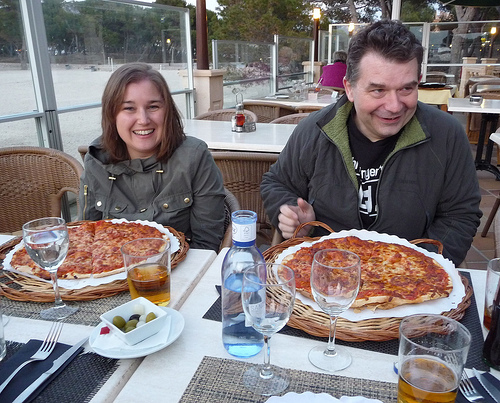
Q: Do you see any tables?
A: Yes, there is a table.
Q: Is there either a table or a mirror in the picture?
A: Yes, there is a table.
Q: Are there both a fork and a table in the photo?
A: Yes, there are both a table and a fork.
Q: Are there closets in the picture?
A: No, there are no closets.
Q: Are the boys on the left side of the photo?
A: Yes, the boys are on the left of the image.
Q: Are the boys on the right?
A: No, the boys are on the left of the image.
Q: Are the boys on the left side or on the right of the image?
A: The boys are on the left of the image.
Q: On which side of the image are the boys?
A: The boys are on the left of the image.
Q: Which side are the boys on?
A: The boys are on the left of the image.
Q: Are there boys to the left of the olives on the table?
A: Yes, there are boys to the left of the olives.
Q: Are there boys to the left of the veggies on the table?
A: Yes, there are boys to the left of the olives.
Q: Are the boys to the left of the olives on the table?
A: Yes, the boys are to the left of the olives.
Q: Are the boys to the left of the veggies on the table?
A: Yes, the boys are to the left of the olives.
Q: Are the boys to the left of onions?
A: No, the boys are to the left of the olives.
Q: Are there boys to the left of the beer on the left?
A: Yes, there are boys to the left of the beer.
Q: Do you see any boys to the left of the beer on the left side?
A: Yes, there are boys to the left of the beer.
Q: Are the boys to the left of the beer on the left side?
A: Yes, the boys are to the left of the beer.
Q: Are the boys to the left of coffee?
A: No, the boys are to the left of the beer.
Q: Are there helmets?
A: No, there are no helmets.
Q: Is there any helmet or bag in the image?
A: No, there are no helmets or bags.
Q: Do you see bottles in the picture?
A: Yes, there is a bottle.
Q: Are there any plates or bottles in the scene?
A: Yes, there is a bottle.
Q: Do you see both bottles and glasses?
A: Yes, there are both a bottle and glasses.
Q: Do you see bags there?
A: No, there are no bags.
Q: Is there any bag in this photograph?
A: No, there are no bags.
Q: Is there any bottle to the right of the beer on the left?
A: Yes, there is a bottle to the right of the beer.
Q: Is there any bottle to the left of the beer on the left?
A: No, the bottle is to the right of the beer.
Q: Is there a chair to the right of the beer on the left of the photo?
A: No, there is a bottle to the right of the beer.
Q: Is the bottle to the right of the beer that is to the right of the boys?
A: Yes, the bottle is to the right of the beer.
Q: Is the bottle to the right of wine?
A: No, the bottle is to the right of the beer.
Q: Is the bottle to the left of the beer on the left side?
A: No, the bottle is to the right of the beer.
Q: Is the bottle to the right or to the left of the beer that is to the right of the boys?
A: The bottle is to the right of the beer.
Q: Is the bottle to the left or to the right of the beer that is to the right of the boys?
A: The bottle is to the right of the beer.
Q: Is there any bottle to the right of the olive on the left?
A: Yes, there is a bottle to the right of the olive.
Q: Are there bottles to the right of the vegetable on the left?
A: Yes, there is a bottle to the right of the olive.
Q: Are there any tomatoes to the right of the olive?
A: No, there is a bottle to the right of the olive.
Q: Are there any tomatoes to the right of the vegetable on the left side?
A: No, there is a bottle to the right of the olive.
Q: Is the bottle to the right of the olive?
A: Yes, the bottle is to the right of the olive.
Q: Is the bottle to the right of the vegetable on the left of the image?
A: Yes, the bottle is to the right of the olive.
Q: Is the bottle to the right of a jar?
A: No, the bottle is to the right of the olive.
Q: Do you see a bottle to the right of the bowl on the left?
A: Yes, there is a bottle to the right of the bowl.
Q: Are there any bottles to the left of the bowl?
A: No, the bottle is to the right of the bowl.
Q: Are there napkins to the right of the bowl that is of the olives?
A: No, there is a bottle to the right of the bowl.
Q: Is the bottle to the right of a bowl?
A: Yes, the bottle is to the right of a bowl.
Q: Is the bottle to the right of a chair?
A: No, the bottle is to the right of a bowl.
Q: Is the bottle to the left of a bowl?
A: No, the bottle is to the right of a bowl.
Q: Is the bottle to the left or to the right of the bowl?
A: The bottle is to the right of the bowl.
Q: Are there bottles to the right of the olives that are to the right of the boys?
A: Yes, there is a bottle to the right of the olives.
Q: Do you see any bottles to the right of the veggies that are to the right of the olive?
A: Yes, there is a bottle to the right of the olives.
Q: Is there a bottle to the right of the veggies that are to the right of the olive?
A: Yes, there is a bottle to the right of the olives.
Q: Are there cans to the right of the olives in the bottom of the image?
A: No, there is a bottle to the right of the olives.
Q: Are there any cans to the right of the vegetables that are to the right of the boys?
A: No, there is a bottle to the right of the olives.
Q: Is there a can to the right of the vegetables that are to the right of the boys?
A: No, there is a bottle to the right of the olives.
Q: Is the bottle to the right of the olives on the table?
A: Yes, the bottle is to the right of the olives.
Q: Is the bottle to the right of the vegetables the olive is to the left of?
A: Yes, the bottle is to the right of the olives.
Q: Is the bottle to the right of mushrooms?
A: No, the bottle is to the right of the olives.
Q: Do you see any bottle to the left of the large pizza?
A: Yes, there is a bottle to the left of the pizza.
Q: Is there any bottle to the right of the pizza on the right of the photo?
A: No, the bottle is to the left of the pizza.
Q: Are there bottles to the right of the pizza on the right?
A: No, the bottle is to the left of the pizza.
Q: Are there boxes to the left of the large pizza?
A: No, there is a bottle to the left of the pizza.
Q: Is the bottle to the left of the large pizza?
A: Yes, the bottle is to the left of the pizza.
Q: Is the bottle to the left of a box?
A: No, the bottle is to the left of the pizza.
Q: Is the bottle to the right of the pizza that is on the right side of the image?
A: No, the bottle is to the left of the pizza.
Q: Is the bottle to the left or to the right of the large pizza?
A: The bottle is to the left of the pizza.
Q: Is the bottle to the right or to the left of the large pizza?
A: The bottle is to the left of the pizza.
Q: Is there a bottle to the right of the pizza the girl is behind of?
A: Yes, there is a bottle to the right of the pizza.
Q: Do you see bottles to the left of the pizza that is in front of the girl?
A: No, the bottle is to the right of the pizza.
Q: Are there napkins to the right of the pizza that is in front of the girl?
A: No, there is a bottle to the right of the pizza.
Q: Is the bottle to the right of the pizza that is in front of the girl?
A: Yes, the bottle is to the right of the pizza.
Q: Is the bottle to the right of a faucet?
A: No, the bottle is to the right of the pizza.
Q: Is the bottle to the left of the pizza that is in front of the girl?
A: No, the bottle is to the right of the pizza.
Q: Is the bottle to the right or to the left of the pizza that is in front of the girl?
A: The bottle is to the right of the pizza.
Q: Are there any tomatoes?
A: No, there are no tomatoes.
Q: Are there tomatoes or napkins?
A: No, there are no tomatoes or napkins.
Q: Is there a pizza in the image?
A: Yes, there is a pizza.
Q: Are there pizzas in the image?
A: Yes, there is a pizza.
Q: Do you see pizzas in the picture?
A: Yes, there is a pizza.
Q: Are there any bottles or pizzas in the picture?
A: Yes, there is a pizza.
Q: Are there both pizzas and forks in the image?
A: Yes, there are both a pizza and a fork.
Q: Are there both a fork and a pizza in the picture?
A: Yes, there are both a pizza and a fork.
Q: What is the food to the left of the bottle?
A: The food is a pizza.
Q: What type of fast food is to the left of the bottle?
A: The food is a pizza.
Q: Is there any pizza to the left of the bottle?
A: Yes, there is a pizza to the left of the bottle.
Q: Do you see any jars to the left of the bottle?
A: No, there is a pizza to the left of the bottle.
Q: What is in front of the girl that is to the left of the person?
A: The pizza is in front of the girl.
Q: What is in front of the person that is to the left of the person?
A: The pizza is in front of the girl.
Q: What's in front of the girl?
A: The pizza is in front of the girl.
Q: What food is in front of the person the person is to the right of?
A: The food is a pizza.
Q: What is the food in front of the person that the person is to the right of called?
A: The food is a pizza.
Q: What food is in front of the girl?
A: The food is a pizza.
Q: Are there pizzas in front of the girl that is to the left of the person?
A: Yes, there is a pizza in front of the girl.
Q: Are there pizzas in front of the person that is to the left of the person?
A: Yes, there is a pizza in front of the girl.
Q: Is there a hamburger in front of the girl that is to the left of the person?
A: No, there is a pizza in front of the girl.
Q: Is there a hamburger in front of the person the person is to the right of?
A: No, there is a pizza in front of the girl.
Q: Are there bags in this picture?
A: No, there are no bags.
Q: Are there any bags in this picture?
A: No, there are no bags.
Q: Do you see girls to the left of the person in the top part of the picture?
A: Yes, there is a girl to the left of the person.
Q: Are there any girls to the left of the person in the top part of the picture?
A: Yes, there is a girl to the left of the person.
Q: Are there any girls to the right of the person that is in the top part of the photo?
A: No, the girl is to the left of the person.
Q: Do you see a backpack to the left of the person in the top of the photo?
A: No, there is a girl to the left of the person.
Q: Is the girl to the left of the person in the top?
A: Yes, the girl is to the left of the person.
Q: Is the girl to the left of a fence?
A: No, the girl is to the left of the person.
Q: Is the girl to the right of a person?
A: No, the girl is to the left of a person.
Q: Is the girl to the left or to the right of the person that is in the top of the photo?
A: The girl is to the left of the person.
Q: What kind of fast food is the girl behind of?
A: The girl is behind the pizza.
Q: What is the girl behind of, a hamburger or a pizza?
A: The girl is behind a pizza.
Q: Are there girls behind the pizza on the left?
A: Yes, there is a girl behind the pizza.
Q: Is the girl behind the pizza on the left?
A: Yes, the girl is behind the pizza.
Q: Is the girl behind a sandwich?
A: No, the girl is behind the pizza.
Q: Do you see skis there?
A: No, there are no skis.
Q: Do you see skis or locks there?
A: No, there are no skis or locks.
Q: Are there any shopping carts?
A: No, there are no shopping carts.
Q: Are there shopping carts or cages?
A: No, there are no shopping carts or cages.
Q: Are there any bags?
A: No, there are no bags.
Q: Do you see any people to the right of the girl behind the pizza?
A: Yes, there is a person to the right of the girl.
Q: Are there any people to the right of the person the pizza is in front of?
A: Yes, there is a person to the right of the girl.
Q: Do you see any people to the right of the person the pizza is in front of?
A: Yes, there is a person to the right of the girl.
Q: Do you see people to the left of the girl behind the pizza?
A: No, the person is to the right of the girl.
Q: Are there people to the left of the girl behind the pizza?
A: No, the person is to the right of the girl.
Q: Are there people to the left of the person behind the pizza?
A: No, the person is to the right of the girl.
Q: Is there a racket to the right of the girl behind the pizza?
A: No, there is a person to the right of the girl.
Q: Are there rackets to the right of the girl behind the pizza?
A: No, there is a person to the right of the girl.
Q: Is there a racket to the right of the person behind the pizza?
A: No, there is a person to the right of the girl.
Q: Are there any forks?
A: Yes, there is a fork.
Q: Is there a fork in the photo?
A: Yes, there is a fork.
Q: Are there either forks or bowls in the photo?
A: Yes, there is a fork.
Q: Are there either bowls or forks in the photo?
A: Yes, there is a fork.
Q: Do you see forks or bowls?
A: Yes, there is a fork.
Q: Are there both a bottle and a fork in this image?
A: Yes, there are both a fork and a bottle.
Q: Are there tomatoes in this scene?
A: No, there are no tomatoes.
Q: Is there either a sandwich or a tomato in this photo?
A: No, there are no tomatoes or sandwiches.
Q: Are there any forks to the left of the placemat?
A: Yes, there is a fork to the left of the placemat.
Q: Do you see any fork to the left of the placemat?
A: Yes, there is a fork to the left of the placemat.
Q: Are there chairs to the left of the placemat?
A: No, there is a fork to the left of the placemat.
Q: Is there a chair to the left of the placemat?
A: No, there is a fork to the left of the placemat.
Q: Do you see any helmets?
A: No, there are no helmets.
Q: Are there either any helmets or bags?
A: No, there are no helmets or bags.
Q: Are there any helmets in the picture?
A: No, there are no helmets.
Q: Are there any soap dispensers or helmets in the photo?
A: No, there are no helmets or soap dispensers.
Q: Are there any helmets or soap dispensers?
A: No, there are no helmets or soap dispensers.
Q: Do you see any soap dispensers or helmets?
A: No, there are no helmets or soap dispensers.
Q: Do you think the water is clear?
A: Yes, the water is clear.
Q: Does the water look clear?
A: Yes, the water is clear.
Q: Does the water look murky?
A: No, the water is clear.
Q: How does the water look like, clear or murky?
A: The water is clear.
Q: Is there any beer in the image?
A: Yes, there is beer.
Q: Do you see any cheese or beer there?
A: Yes, there is beer.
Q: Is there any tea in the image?
A: No, there is no tea.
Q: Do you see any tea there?
A: No, there is no tea.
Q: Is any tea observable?
A: No, there is no tea.